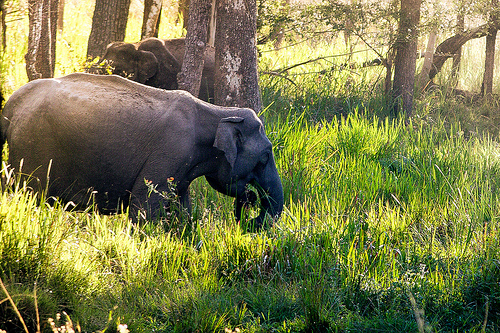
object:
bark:
[395, 0, 419, 112]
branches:
[303, 6, 381, 33]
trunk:
[210, 0, 262, 106]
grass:
[294, 120, 340, 166]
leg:
[127, 173, 166, 229]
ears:
[212, 114, 245, 173]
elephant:
[88, 37, 195, 93]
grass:
[369, 135, 461, 200]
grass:
[8, 223, 64, 329]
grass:
[344, 121, 386, 163]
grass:
[391, 229, 493, 322]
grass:
[223, 244, 305, 331]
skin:
[81, 122, 136, 148]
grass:
[266, 97, 339, 123]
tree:
[208, 0, 260, 109]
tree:
[176, 0, 213, 102]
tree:
[83, 0, 133, 87]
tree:
[139, 1, 161, 46]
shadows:
[0, 223, 500, 332]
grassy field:
[1, 0, 500, 331]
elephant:
[4, 72, 286, 240]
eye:
[256, 157, 269, 169]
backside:
[1, 78, 62, 200]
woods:
[0, 0, 499, 120]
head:
[100, 35, 150, 91]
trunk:
[232, 180, 296, 233]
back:
[50, 70, 195, 110]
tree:
[393, 0, 421, 116]